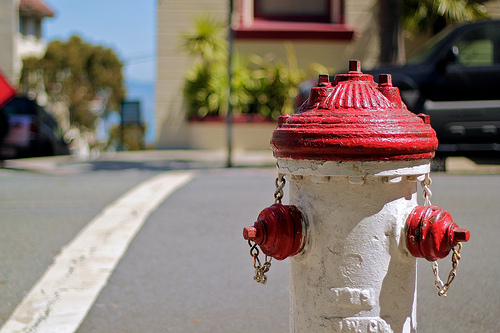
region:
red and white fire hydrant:
[239, 56, 472, 328]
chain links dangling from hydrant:
[419, 174, 463, 302]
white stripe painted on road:
[8, 168, 203, 330]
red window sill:
[231, 19, 356, 47]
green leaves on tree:
[40, 34, 123, 125]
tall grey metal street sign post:
[222, 1, 236, 169]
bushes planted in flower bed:
[180, 18, 322, 117]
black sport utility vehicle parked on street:
[336, 20, 498, 169]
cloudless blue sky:
[41, 0, 154, 85]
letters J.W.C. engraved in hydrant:
[329, 316, 379, 331]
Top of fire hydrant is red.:
[283, 59, 420, 147]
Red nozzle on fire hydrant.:
[391, 205, 471, 275]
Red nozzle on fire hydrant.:
[257, 188, 299, 265]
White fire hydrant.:
[269, 143, 418, 331]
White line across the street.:
[74, 150, 119, 326]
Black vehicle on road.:
[394, 37, 486, 112]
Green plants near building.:
[168, 30, 310, 134]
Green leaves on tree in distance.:
[40, 48, 120, 138]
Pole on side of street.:
[204, 30, 246, 193]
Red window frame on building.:
[237, 8, 379, 69]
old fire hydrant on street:
[228, 71, 455, 332]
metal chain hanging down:
[410, 252, 465, 294]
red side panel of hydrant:
[398, 201, 476, 269]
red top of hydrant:
[284, 66, 431, 157]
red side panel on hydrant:
[232, 199, 304, 267]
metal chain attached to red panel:
[240, 246, 267, 287]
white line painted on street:
[32, 165, 210, 332]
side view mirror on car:
[424, 36, 481, 73]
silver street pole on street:
[220, 0, 234, 172]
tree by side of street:
[24, 28, 136, 155]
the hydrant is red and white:
[230, 61, 486, 327]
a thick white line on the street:
[16, 155, 190, 327]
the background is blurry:
[12, 33, 242, 145]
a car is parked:
[341, 15, 498, 182]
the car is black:
[340, 13, 493, 129]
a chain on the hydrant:
[393, 164, 461, 316]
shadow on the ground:
[32, 137, 234, 189]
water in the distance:
[95, 50, 156, 145]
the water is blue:
[117, 72, 177, 137]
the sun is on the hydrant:
[337, 176, 470, 323]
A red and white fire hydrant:
[232, 48, 464, 332]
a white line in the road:
[7, 138, 191, 313]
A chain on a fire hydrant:
[222, 153, 297, 278]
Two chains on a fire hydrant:
[230, 156, 475, 301]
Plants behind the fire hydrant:
[180, 20, 338, 130]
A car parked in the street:
[295, 28, 496, 169]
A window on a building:
[217, 2, 381, 40]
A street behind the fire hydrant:
[17, 158, 495, 329]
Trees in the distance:
[12, 28, 127, 136]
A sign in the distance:
[112, 92, 150, 160]